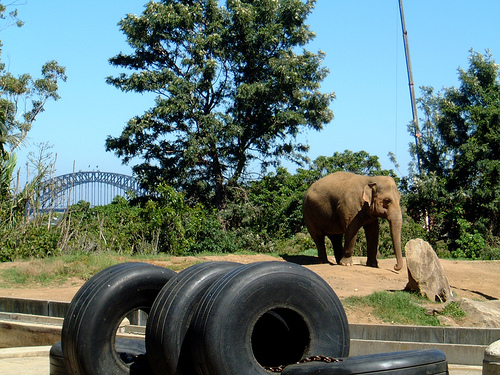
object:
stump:
[403, 237, 435, 283]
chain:
[293, 351, 345, 365]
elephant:
[301, 169, 402, 272]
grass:
[0, 252, 214, 289]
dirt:
[0, 254, 500, 329]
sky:
[0, 0, 500, 210]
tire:
[282, 349, 449, 374]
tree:
[0, 0, 69, 233]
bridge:
[13, 170, 166, 213]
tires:
[60, 257, 180, 374]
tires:
[145, 259, 246, 375]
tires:
[193, 258, 352, 373]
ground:
[0, 253, 499, 375]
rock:
[403, 236, 453, 305]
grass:
[340, 288, 468, 327]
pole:
[397, 0, 430, 232]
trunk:
[388, 209, 404, 273]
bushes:
[0, 149, 500, 261]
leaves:
[258, 0, 278, 26]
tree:
[407, 48, 500, 243]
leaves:
[473, 102, 498, 124]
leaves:
[459, 230, 487, 248]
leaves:
[350, 152, 373, 171]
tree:
[307, 149, 391, 178]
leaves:
[264, 193, 292, 209]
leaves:
[165, 15, 183, 27]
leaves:
[126, 21, 146, 38]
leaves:
[135, 75, 160, 91]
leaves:
[294, 60, 318, 79]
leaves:
[305, 95, 327, 116]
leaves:
[280, 0, 302, 19]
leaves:
[476, 64, 495, 82]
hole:
[250, 306, 314, 373]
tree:
[102, 0, 333, 233]